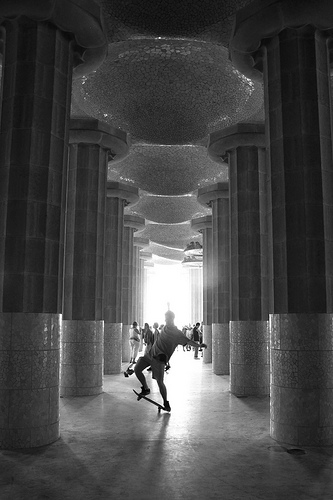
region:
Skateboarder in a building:
[118, 292, 192, 416]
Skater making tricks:
[125, 292, 198, 428]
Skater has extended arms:
[116, 293, 213, 417]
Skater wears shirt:
[116, 291, 215, 429]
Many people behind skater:
[120, 314, 205, 353]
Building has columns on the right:
[182, 93, 331, 467]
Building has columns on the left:
[12, 58, 145, 447]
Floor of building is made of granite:
[43, 355, 290, 498]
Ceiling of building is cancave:
[80, 40, 239, 294]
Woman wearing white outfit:
[122, 317, 144, 368]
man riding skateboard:
[134, 386, 171, 415]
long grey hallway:
[199, 386, 241, 479]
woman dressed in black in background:
[128, 318, 141, 364]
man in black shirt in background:
[190, 321, 203, 339]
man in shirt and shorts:
[136, 310, 172, 400]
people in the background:
[139, 316, 158, 338]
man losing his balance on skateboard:
[137, 309, 183, 406]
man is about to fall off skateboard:
[135, 307, 179, 411]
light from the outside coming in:
[149, 275, 185, 304]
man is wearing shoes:
[138, 386, 152, 403]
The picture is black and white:
[101, 205, 298, 395]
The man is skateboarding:
[132, 284, 196, 445]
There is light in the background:
[137, 243, 218, 374]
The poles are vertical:
[204, 212, 314, 438]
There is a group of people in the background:
[135, 294, 225, 419]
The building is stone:
[44, 296, 265, 475]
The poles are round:
[194, 215, 329, 422]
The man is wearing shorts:
[138, 285, 192, 411]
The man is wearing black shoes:
[116, 335, 209, 458]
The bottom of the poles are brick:
[265, 288, 331, 435]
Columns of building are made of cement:
[185, 95, 327, 456]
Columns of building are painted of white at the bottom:
[192, 312, 329, 474]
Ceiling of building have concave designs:
[73, 33, 260, 147]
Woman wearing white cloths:
[122, 317, 140, 362]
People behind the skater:
[117, 323, 204, 361]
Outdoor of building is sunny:
[145, 264, 190, 325]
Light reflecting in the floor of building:
[136, 342, 234, 460]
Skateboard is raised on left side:
[118, 382, 170, 421]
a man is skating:
[131, 305, 206, 414]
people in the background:
[128, 310, 205, 368]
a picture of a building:
[4, 3, 331, 498]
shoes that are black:
[133, 383, 171, 414]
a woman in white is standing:
[129, 320, 140, 366]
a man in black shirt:
[190, 320, 201, 357]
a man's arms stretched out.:
[130, 301, 207, 413]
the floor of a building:
[1, 356, 332, 497]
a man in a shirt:
[132, 298, 207, 413]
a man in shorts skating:
[127, 299, 209, 412]